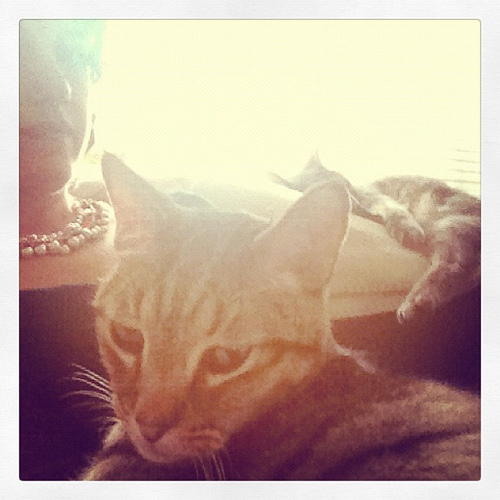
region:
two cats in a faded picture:
[109, 113, 453, 445]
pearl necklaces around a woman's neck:
[27, 198, 106, 253]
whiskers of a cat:
[56, 353, 145, 429]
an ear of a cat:
[250, 157, 355, 290]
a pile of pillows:
[200, 156, 464, 300]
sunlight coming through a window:
[107, 33, 410, 147]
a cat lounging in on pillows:
[247, 134, 472, 309]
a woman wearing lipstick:
[23, 115, 93, 150]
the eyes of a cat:
[102, 315, 279, 400]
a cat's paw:
[378, 258, 456, 330]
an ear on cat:
[262, 189, 351, 272]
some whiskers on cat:
[72, 370, 124, 432]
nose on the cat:
[134, 402, 167, 436]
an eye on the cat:
[203, 343, 253, 377]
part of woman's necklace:
[27, 232, 100, 250]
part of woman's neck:
[26, 197, 73, 221]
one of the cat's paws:
[397, 220, 427, 250]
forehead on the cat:
[142, 263, 225, 300]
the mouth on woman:
[25, 126, 76, 142]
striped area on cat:
[331, 392, 443, 459]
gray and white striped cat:
[62, 143, 430, 473]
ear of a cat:
[255, 177, 361, 300]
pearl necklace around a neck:
[25, 190, 110, 272]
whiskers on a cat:
[54, 351, 135, 450]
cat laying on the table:
[263, 120, 473, 331]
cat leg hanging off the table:
[387, 245, 482, 342]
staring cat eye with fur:
[190, 327, 276, 392]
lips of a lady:
[18, 110, 85, 155]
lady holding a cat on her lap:
[23, 27, 414, 473]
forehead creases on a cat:
[111, 277, 255, 344]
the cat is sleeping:
[300, 138, 476, 350]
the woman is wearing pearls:
[15, 30, 120, 277]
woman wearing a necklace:
[9, 163, 149, 313]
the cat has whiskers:
[61, 347, 231, 464]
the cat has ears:
[65, 135, 379, 344]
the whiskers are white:
[57, 329, 285, 494]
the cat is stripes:
[83, 219, 424, 454]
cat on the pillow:
[280, 141, 491, 377]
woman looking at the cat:
[10, 22, 350, 462]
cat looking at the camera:
[86, 302, 296, 422]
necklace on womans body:
[27, 181, 115, 247]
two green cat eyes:
[103, 276, 288, 412]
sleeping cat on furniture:
[303, 145, 428, 235]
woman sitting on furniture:
[27, 27, 112, 185]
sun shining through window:
[151, 41, 392, 161]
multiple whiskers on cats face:
[75, 305, 275, 455]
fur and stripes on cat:
[126, 201, 368, 439]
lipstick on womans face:
[27, 66, 117, 202]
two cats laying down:
[105, 106, 430, 401]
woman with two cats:
[23, 36, 465, 419]